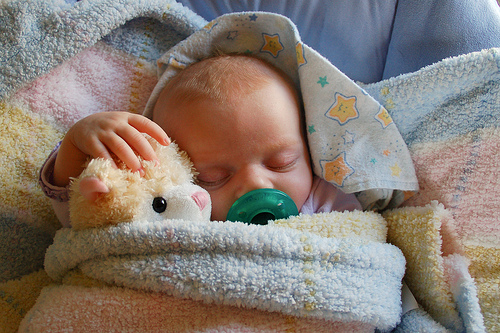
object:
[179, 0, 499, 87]
pillow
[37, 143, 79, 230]
sleeve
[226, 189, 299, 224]
pacifier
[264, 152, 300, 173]
eye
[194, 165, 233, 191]
eye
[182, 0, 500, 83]
pad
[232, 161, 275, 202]
nose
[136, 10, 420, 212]
cloth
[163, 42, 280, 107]
hair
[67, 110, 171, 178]
baby's hand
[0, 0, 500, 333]
baby blanket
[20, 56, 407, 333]
baby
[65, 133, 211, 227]
bear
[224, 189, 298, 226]
mouth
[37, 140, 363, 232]
gament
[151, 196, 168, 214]
eye